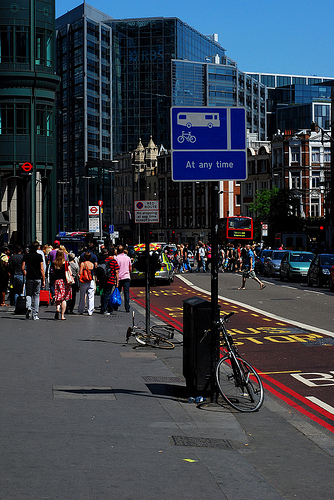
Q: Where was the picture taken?
A: In a city.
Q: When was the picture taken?
A: Daytime.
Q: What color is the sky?
A: Blue.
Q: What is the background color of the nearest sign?
A: Blue.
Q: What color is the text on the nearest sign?
A: White.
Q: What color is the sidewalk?
A: Gray.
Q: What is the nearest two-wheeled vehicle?
A: A bicycle.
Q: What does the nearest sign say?
A: At any time.